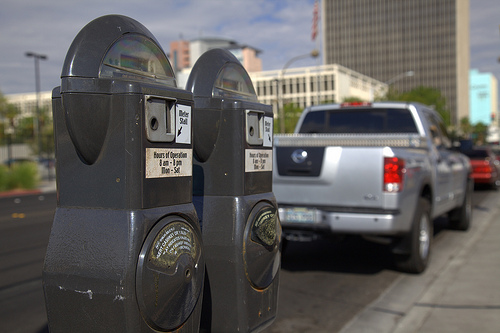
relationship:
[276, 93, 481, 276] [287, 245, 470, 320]
truck on street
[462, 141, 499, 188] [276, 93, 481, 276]
vehicle in front truck.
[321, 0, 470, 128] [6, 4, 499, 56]
building are in background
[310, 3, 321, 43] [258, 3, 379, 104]
american flag on building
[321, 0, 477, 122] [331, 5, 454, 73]
building with windows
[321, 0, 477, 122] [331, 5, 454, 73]
building with many windows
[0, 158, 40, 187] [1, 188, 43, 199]
green plant on a clay planter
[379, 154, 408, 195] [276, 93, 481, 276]
tail light of truck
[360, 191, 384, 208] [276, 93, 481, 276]
logo on truck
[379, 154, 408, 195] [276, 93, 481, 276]
tale light of silver truck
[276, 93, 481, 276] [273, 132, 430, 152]
truck has toolbox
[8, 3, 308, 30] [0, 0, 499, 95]
clouds in sky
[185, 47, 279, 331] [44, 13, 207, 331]
parking meter next to parking meter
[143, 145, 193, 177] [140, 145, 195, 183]
sign on meter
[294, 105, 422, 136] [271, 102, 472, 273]
window on truck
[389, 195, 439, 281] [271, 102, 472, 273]
tire on truck